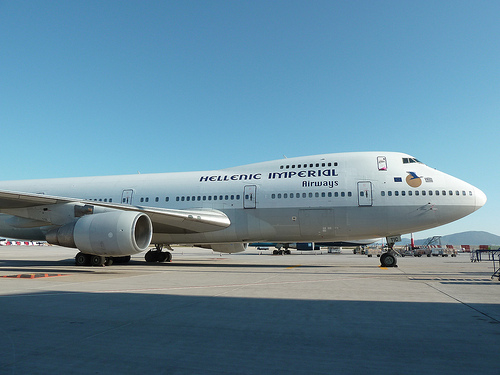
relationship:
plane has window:
[0, 147, 487, 267] [334, 192, 341, 199]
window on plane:
[334, 192, 341, 199] [0, 147, 487, 267]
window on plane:
[214, 194, 219, 200] [0, 147, 487, 267]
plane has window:
[0, 147, 487, 267] [165, 197, 170, 204]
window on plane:
[403, 157, 420, 165] [0, 147, 487, 267]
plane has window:
[0, 147, 487, 267] [192, 196, 197, 202]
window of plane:
[296, 193, 301, 199] [0, 147, 487, 267]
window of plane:
[144, 197, 149, 202] [0, 147, 487, 267]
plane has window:
[0, 147, 487, 267] [198, 196, 202, 203]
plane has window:
[0, 147, 487, 267] [202, 196, 208, 201]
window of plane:
[219, 194, 224, 201] [0, 147, 487, 267]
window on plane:
[230, 194, 236, 201] [0, 147, 487, 267]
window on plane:
[236, 194, 243, 202] [0, 147, 487, 267]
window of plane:
[272, 193, 277, 199] [0, 147, 487, 267]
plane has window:
[0, 147, 487, 267] [276, 191, 283, 199]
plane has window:
[0, 147, 487, 267] [284, 192, 289, 198]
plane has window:
[0, 147, 487, 267] [288, 193, 294, 200]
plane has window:
[0, 147, 487, 267] [302, 193, 307, 198]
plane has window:
[0, 147, 487, 267] [309, 192, 314, 199]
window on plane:
[315, 192, 320, 199] [0, 147, 487, 267]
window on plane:
[321, 192, 327, 199] [0, 147, 487, 267]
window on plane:
[327, 191, 333, 198] [0, 147, 487, 267]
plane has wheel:
[0, 147, 487, 267] [380, 252, 396, 266]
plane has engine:
[0, 147, 487, 267] [43, 210, 152, 258]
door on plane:
[242, 185, 257, 210] [0, 147, 487, 267]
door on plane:
[357, 181, 374, 208] [0, 147, 487, 267]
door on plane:
[121, 189, 134, 203] [0, 147, 487, 267]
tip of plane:
[410, 156, 487, 231] [0, 147, 487, 267]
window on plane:
[224, 194, 230, 201] [0, 147, 487, 267]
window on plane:
[203, 194, 208, 201] [0, 147, 487, 267]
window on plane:
[186, 197, 191, 202] [0, 147, 487, 267]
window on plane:
[181, 196, 186, 201] [0, 147, 487, 267]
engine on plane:
[43, 210, 152, 258] [0, 147, 487, 267]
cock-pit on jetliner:
[375, 151, 422, 180] [0, 147, 487, 267]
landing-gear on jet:
[75, 242, 403, 271] [0, 147, 487, 267]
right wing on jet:
[1, 190, 230, 235] [0, 147, 487, 267]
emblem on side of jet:
[406, 171, 423, 189] [0, 147, 487, 267]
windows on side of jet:
[85, 190, 474, 203] [0, 147, 487, 267]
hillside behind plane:
[400, 229, 499, 251] [0, 147, 487, 267]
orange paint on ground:
[1, 272, 68, 280] [0, 246, 500, 375]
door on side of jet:
[242, 185, 257, 210] [0, 147, 487, 267]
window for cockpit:
[403, 157, 420, 165] [375, 151, 422, 180]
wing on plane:
[1, 190, 230, 235] [0, 147, 487, 267]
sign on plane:
[406, 171, 423, 189] [0, 147, 487, 267]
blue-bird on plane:
[406, 171, 423, 181] [0, 147, 487, 267]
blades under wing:
[43, 210, 152, 258] [1, 190, 230, 235]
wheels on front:
[380, 252, 396, 266] [276, 150, 487, 244]